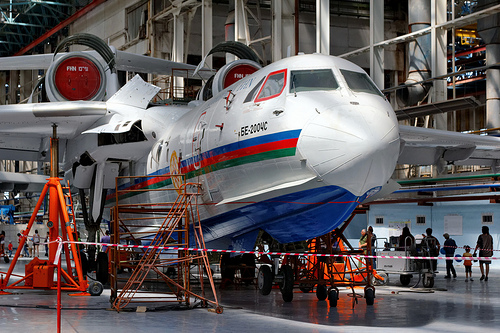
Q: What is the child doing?
A: Holding adult's hand.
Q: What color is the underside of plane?
A: Blue.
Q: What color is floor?
A: White.